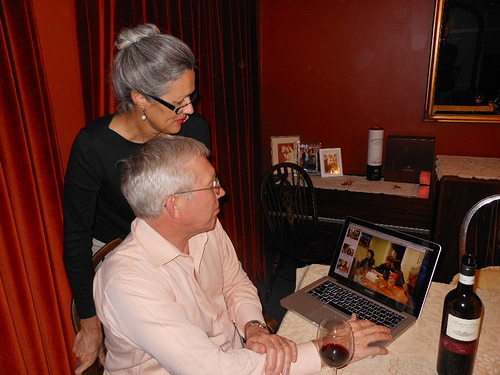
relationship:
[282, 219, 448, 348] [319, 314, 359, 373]
laptop near glass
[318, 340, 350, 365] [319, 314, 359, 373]
wine in glass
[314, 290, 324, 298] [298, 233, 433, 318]
key on laptop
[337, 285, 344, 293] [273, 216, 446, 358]
black key on laptop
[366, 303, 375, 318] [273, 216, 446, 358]
black key on laptop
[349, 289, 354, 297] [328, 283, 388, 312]
key on laptop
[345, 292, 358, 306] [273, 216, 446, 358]
key on laptop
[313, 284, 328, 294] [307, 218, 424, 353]
black key on laptop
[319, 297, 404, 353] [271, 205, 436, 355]
key on laptop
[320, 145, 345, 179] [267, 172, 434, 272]
knick knack on cabinet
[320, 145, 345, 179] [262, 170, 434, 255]
knick knack on cabinet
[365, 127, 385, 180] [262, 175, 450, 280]
knick knack on cabinet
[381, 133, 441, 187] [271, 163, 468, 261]
nick knack on cabinet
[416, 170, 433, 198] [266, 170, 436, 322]
nick knack on cabinet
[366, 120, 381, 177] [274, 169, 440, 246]
nick knack on wooden cabinet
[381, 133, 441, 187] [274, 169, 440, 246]
nick knack on wooden cabinet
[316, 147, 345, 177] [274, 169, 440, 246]
nick knack on wooden cabinet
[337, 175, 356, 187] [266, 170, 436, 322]
knick knack on cabinet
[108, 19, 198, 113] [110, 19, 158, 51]
gray hair in bun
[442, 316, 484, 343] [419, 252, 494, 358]
label on wine bottle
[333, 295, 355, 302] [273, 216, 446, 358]
keys on laptop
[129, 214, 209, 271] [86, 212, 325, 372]
collar on collarshirt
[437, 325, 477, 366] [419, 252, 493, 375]
wine in wine bottle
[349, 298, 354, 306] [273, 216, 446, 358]
key on laptop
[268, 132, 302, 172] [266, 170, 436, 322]
nick knack on a cabinet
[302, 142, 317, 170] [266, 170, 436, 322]
nick knack on a cabinet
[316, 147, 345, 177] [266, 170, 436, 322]
nick knack on a cabinet